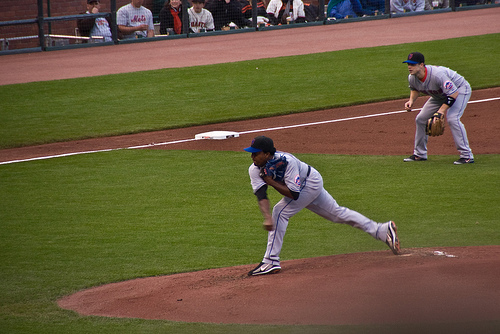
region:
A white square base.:
[194, 129, 239, 140]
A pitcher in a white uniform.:
[247, 134, 398, 275]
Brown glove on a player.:
[427, 112, 444, 137]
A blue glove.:
[262, 157, 288, 182]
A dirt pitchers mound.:
[57, 245, 499, 332]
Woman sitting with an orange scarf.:
[160, 0, 190, 34]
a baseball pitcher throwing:
[243, 135, 400, 275]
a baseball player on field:
[400, 50, 474, 163]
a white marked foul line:
[0, 95, 497, 164]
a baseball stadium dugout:
[3, 0, 498, 52]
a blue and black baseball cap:
[244, 135, 273, 152]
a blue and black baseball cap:
[400, 51, 424, 65]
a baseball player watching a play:
[383, 36, 480, 176]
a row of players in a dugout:
[62, 0, 494, 47]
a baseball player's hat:
[387, 45, 438, 70]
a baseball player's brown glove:
[415, 102, 452, 147]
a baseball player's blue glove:
[243, 147, 292, 184]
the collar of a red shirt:
[411, 61, 440, 91]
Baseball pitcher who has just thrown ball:
[243, 133, 401, 275]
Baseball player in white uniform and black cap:
[244, 134, 401, 278]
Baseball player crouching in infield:
[401, 50, 476, 165]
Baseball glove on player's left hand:
[424, 112, 446, 137]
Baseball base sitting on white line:
[194, 128, 239, 141]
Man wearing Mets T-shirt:
[117, 0, 155, 40]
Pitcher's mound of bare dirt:
[56, 242, 498, 332]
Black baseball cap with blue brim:
[243, 134, 276, 153]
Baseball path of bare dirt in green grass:
[1, 81, 498, 168]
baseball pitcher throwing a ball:
[245, 135, 398, 275]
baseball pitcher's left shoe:
[381, 219, 401, 253]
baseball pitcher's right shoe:
[247, 260, 281, 275]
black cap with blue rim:
[245, 134, 275, 151]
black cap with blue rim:
[402, 51, 424, 63]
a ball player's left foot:
[450, 150, 473, 163]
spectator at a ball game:
[115, 0, 152, 41]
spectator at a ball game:
[187, 0, 214, 34]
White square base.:
[194, 127, 239, 140]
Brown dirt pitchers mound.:
[57, 242, 499, 332]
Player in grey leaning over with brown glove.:
[404, 52, 474, 164]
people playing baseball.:
[187, 20, 492, 321]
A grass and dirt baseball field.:
[32, 6, 497, 329]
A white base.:
[192, 129, 241, 144]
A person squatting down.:
[397, 46, 478, 166]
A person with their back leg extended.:
[236, 123, 408, 273]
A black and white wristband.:
[437, 91, 461, 110]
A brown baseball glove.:
[425, 109, 444, 139]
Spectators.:
[75, 1, 454, 43]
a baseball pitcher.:
[242, 134, 404, 281]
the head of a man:
[241, 129, 273, 173]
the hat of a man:
[240, 129, 271, 159]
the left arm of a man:
[254, 156, 312, 203]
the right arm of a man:
[240, 171, 281, 235]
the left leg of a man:
[265, 185, 322, 263]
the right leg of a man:
[308, 183, 410, 261]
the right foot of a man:
[381, 219, 409, 254]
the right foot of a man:
[247, 255, 288, 279]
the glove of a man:
[420, 108, 448, 145]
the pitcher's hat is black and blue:
[242, 129, 279, 163]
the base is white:
[190, 123, 240, 145]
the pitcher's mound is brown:
[53, 243, 498, 333]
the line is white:
[0, 93, 496, 164]